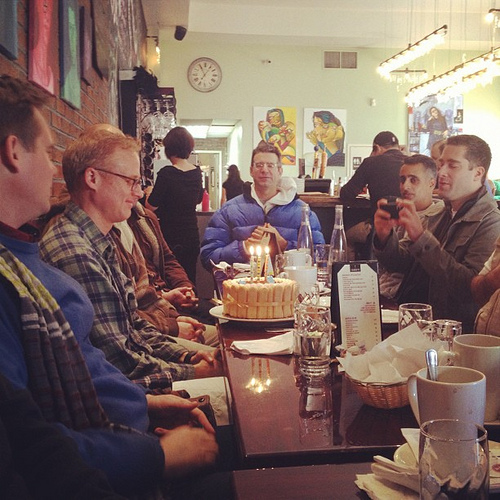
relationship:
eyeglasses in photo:
[249, 156, 288, 172] [3, 7, 494, 496]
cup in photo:
[415, 365, 488, 445] [3, 7, 494, 496]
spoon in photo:
[427, 352, 443, 378] [3, 7, 494, 496]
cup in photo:
[294, 307, 333, 367] [3, 7, 494, 496]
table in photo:
[208, 264, 498, 457] [3, 7, 494, 496]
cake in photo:
[211, 273, 301, 324] [3, 7, 494, 496]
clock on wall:
[184, 53, 225, 100] [143, 30, 404, 182]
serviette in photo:
[236, 330, 306, 353] [3, 7, 494, 496]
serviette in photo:
[373, 457, 440, 495] [3, 7, 494, 496]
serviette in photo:
[209, 258, 251, 278] [3, 7, 494, 496]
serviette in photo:
[213, 259, 238, 272] [3, 7, 494, 496]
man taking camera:
[419, 139, 493, 330] [380, 196, 403, 219]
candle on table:
[266, 243, 274, 286] [208, 264, 498, 457]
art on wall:
[247, 100, 300, 170] [143, 30, 404, 182]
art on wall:
[302, 102, 351, 180] [143, 30, 404, 182]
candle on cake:
[266, 243, 274, 286] [211, 273, 301, 324]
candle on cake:
[255, 243, 266, 289] [211, 273, 301, 324]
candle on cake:
[241, 245, 256, 284] [211, 273, 301, 324]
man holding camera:
[419, 139, 493, 330] [380, 193, 411, 219]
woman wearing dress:
[168, 129, 211, 270] [151, 167, 208, 267]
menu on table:
[329, 260, 385, 351] [208, 264, 498, 457]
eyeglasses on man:
[249, 156, 288, 172] [233, 149, 317, 260]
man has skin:
[69, 126, 172, 370] [99, 161, 135, 227]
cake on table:
[211, 273, 301, 324] [208, 264, 498, 457]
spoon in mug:
[427, 352, 443, 378] [415, 365, 488, 445]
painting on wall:
[247, 100, 300, 170] [143, 30, 404, 182]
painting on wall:
[302, 102, 351, 180] [143, 30, 404, 182]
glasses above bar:
[144, 93, 175, 132] [130, 70, 173, 186]